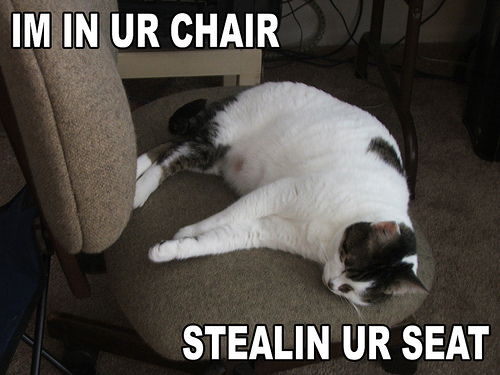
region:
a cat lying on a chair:
[108, 68, 431, 320]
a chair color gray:
[10, 5, 457, 363]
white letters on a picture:
[8, 9, 493, 374]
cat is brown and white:
[127, 63, 434, 317]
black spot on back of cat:
[335, 105, 420, 187]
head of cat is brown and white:
[319, 215, 431, 314]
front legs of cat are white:
[144, 176, 299, 269]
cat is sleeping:
[127, 64, 432, 316]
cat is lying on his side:
[134, 71, 431, 318]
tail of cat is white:
[161, 83, 256, 140]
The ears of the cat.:
[363, 205, 433, 287]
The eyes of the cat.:
[341, 256, 368, 303]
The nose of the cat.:
[326, 277, 341, 290]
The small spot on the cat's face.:
[342, 283, 359, 297]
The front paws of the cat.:
[144, 214, 204, 269]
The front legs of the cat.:
[195, 182, 300, 253]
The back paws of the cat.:
[135, 150, 147, 205]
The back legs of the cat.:
[149, 128, 216, 183]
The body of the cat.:
[216, 84, 410, 233]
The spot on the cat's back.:
[367, 135, 405, 180]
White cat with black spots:
[130, 77, 430, 325]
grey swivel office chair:
[5, 0, 431, 370]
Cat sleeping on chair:
[125, 76, 432, 313]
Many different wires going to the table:
[267, 0, 444, 70]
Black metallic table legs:
[348, 3, 462, 202]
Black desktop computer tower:
[459, 2, 498, 162]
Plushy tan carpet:
[0, 54, 499, 373]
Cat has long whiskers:
[122, 75, 433, 329]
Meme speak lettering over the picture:
[7, 9, 285, 54]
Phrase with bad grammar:
[172, 317, 492, 370]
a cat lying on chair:
[125, 71, 430, 316]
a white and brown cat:
[125, 67, 435, 312]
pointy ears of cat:
[360, 212, 430, 302]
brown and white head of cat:
[312, 216, 427, 311]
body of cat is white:
[225, 80, 415, 212]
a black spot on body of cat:
[351, 111, 407, 181]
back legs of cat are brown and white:
[123, 122, 213, 208]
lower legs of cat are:
[126, 154, 162, 214]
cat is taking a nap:
[135, 47, 435, 329]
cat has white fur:
[204, 85, 419, 270]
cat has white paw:
[158, 223, 205, 268]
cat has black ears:
[334, 215, 429, 304]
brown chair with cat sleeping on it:
[10, 4, 442, 361]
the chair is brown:
[8, 61, 446, 363]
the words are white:
[174, 313, 488, 373]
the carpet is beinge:
[431, 170, 498, 361]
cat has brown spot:
[363, 132, 410, 179]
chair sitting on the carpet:
[9, 11, 429, 368]